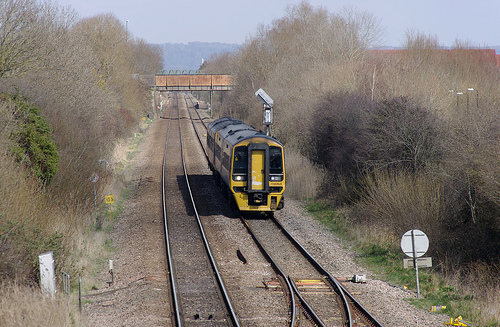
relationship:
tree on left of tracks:
[0, 83, 62, 198] [153, 88, 245, 325]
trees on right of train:
[312, 53, 459, 187] [192, 99, 294, 227]